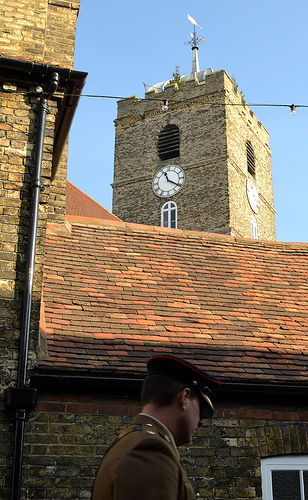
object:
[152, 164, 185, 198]
clock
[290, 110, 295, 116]
lightbulb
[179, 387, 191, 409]
ear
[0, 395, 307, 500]
bricks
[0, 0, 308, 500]
house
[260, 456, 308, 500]
window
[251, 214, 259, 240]
window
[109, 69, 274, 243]
building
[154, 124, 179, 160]
window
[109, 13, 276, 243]
tower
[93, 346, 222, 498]
man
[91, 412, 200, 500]
uniform